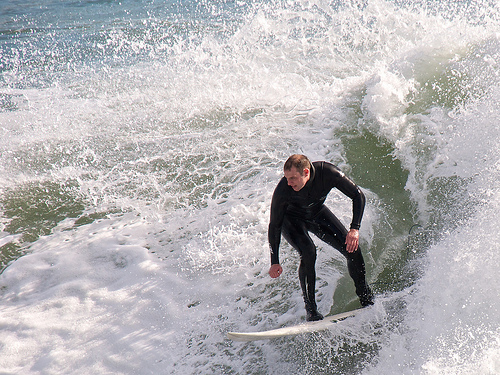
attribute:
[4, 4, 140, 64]
blue water — clear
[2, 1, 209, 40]
section — calm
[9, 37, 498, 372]
wave — white